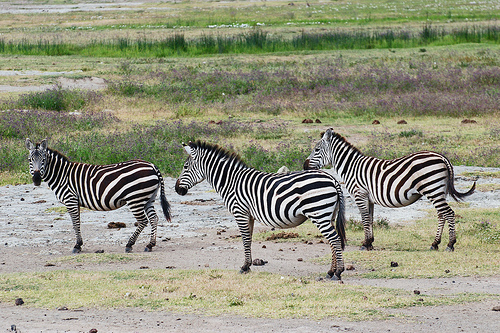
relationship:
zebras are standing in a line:
[24, 128, 477, 281] [28, 159, 465, 168]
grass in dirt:
[9, 267, 422, 318] [0, 164, 499, 332]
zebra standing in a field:
[24, 137, 170, 253] [1, 1, 499, 330]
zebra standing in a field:
[175, 140, 349, 280] [1, 1, 499, 330]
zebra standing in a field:
[303, 127, 477, 251] [1, 1, 499, 330]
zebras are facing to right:
[24, 128, 477, 281] [1, 5, 5, 332]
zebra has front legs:
[24, 137, 170, 253] [64, 201, 84, 255]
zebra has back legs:
[24, 137, 170, 253] [125, 205, 159, 246]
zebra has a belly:
[175, 140, 349, 280] [250, 207, 306, 229]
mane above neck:
[189, 141, 250, 168] [203, 146, 232, 206]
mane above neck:
[37, 145, 72, 162] [42, 145, 68, 203]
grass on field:
[0, 30, 499, 66] [1, 1, 500, 333]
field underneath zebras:
[1, 1, 500, 333] [24, 128, 477, 281]